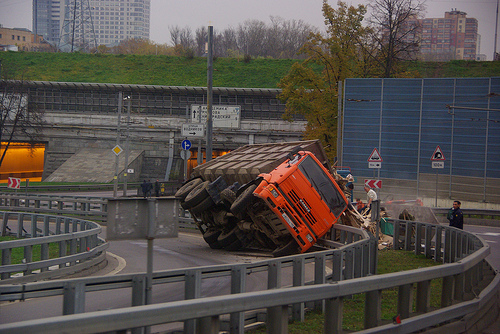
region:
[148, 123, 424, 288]
the truck is orange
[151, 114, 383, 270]
a truck is in the photo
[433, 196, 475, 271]
a person is standing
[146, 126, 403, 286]
the truck has slunted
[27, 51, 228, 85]
the grass is green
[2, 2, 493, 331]
the photo was taken outside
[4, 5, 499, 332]
the photo was taken during the day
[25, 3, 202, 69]
buildings are in the photo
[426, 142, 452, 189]
sign posts are in the photo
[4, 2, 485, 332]
the photo is clear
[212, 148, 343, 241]
truck has fallen down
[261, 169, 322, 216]
truck is orange in color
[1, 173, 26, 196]
arrow board is white and red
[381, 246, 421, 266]
grass is green in color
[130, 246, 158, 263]
grey color road.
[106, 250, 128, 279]
white lines are drawn in the road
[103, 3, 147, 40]
building is white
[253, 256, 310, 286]
fence is grey in color.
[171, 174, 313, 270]
truck has 10 wheels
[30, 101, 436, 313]
daytime picture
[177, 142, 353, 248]
an orange and brown truck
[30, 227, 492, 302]
three metal railings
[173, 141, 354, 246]
a truck on its side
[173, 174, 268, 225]
wheels of the truck off the ground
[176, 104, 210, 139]
two black arrows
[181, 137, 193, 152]
a blue and white arrow sign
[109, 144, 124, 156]
a white and yellow triangle sign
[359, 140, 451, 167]
two triangle signs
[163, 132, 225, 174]
lights on in an underpass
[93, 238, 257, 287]
Road way with guard rails.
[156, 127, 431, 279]
Accident on the roadway.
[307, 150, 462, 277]
Workers cleaning up the accident.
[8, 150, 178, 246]
Sharp turn warning sign.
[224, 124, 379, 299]
Orange truck on it's side.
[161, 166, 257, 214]
Truck tires in the air.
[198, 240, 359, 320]
Guard rails.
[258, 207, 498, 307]
Grass between the guard rails.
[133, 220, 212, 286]
Gray road.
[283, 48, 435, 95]
Tree with leaves.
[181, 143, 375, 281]
a lorry has over turned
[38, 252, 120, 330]
road rails are present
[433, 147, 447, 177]
this is a road sign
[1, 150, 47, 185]
an underpass tunnel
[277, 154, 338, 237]
the truck is orange in colour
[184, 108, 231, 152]
this are road signs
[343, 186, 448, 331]
goods from the overturned truck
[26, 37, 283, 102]
green vegetation the image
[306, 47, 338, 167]
a tree on the image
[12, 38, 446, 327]
what a nice shot